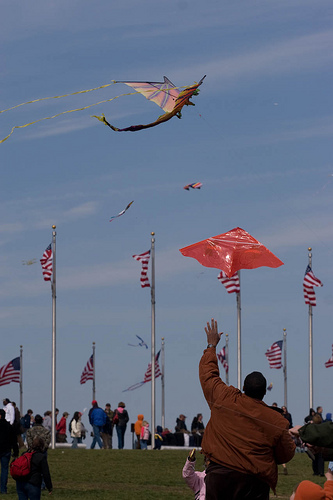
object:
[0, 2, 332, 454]
sky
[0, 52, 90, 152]
clouds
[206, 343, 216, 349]
watch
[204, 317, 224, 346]
hand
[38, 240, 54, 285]
flag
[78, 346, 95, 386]
flag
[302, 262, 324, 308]
flag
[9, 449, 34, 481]
red backpack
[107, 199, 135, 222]
kite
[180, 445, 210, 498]
child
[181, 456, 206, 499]
jacket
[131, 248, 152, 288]
flag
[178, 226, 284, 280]
kite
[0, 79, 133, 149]
ribbons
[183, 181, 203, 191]
kite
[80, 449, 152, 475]
grass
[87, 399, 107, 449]
people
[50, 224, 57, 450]
flag pole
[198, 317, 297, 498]
man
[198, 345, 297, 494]
brown jacket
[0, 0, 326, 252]
air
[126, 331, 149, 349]
kite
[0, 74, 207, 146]
dragon kite